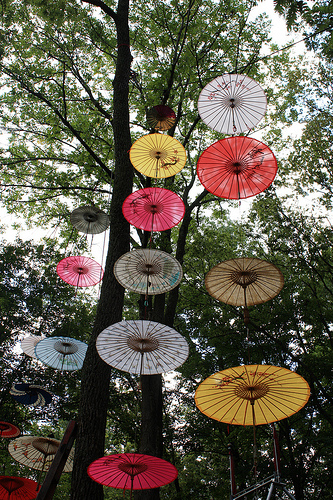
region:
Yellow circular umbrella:
[194, 362, 311, 424]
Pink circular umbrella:
[86, 451, 180, 490]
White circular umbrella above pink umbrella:
[93, 321, 190, 372]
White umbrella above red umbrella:
[197, 75, 266, 130]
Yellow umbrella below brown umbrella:
[192, 360, 313, 422]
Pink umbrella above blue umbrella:
[57, 255, 103, 284]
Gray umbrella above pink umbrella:
[67, 206, 111, 232]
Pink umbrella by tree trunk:
[121, 187, 187, 230]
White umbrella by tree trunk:
[95, 316, 189, 374]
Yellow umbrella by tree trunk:
[128, 135, 186, 180]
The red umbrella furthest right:
[192, 133, 282, 204]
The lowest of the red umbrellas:
[0, 470, 47, 499]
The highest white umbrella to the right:
[192, 69, 272, 137]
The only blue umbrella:
[34, 331, 89, 374]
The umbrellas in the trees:
[0, 70, 311, 499]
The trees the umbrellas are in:
[0, 0, 332, 499]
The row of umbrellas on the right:
[192, 74, 313, 452]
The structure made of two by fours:
[222, 424, 298, 499]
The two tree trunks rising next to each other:
[68, 1, 221, 497]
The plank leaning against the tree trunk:
[27, 418, 77, 499]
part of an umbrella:
[133, 138, 150, 154]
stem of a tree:
[138, 409, 159, 429]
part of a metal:
[218, 462, 234, 495]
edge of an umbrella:
[140, 448, 157, 462]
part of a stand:
[229, 449, 251, 471]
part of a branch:
[176, 433, 198, 457]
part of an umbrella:
[133, 458, 153, 475]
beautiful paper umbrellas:
[0, 84, 313, 498]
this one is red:
[90, 441, 182, 497]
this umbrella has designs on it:
[197, 351, 317, 468]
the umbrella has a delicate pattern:
[91, 313, 210, 391]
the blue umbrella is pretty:
[30, 317, 96, 398]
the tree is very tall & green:
[26, 80, 143, 190]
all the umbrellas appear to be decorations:
[1, 139, 304, 497]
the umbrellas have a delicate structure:
[178, 369, 317, 431]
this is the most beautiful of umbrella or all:
[116, 183, 205, 237]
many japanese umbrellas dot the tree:
[2, 45, 332, 441]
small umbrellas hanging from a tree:
[0, 62, 313, 498]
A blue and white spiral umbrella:
[2, 373, 57, 415]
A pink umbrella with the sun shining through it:
[45, 249, 108, 290]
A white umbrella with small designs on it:
[83, 314, 193, 377]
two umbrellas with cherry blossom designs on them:
[127, 130, 188, 232]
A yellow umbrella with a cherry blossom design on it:
[186, 361, 316, 430]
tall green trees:
[0, 45, 127, 201]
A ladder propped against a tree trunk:
[38, 419, 79, 498]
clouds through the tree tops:
[1, 0, 332, 76]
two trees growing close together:
[74, 244, 185, 473]